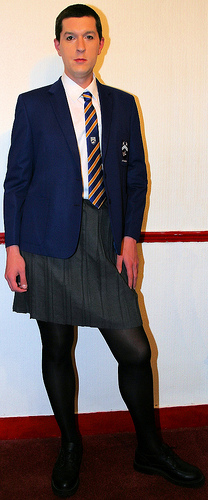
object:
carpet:
[172, 416, 193, 446]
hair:
[51, 2, 103, 38]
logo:
[87, 133, 98, 146]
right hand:
[3, 243, 28, 293]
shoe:
[55, 449, 80, 493]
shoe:
[136, 441, 206, 479]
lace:
[161, 447, 181, 466]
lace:
[60, 445, 73, 463]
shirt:
[59, 72, 113, 201]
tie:
[82, 90, 107, 210]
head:
[56, 3, 103, 75]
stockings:
[37, 320, 158, 439]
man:
[0, 0, 202, 484]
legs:
[40, 252, 84, 497]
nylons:
[35, 327, 157, 443]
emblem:
[90, 136, 96, 145]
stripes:
[82, 154, 101, 183]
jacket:
[3, 78, 148, 256]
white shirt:
[61, 75, 109, 202]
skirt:
[7, 197, 145, 330]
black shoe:
[137, 444, 203, 485]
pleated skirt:
[9, 194, 155, 333]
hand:
[118, 240, 140, 287]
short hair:
[53, 2, 103, 37]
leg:
[89, 231, 172, 447]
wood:
[1, 230, 207, 243]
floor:
[2, 437, 207, 499]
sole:
[130, 458, 206, 490]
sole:
[53, 444, 81, 495]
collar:
[59, 70, 99, 105]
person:
[4, 0, 207, 500]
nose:
[75, 38, 85, 52]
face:
[57, 10, 100, 75]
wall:
[1, 0, 207, 418]